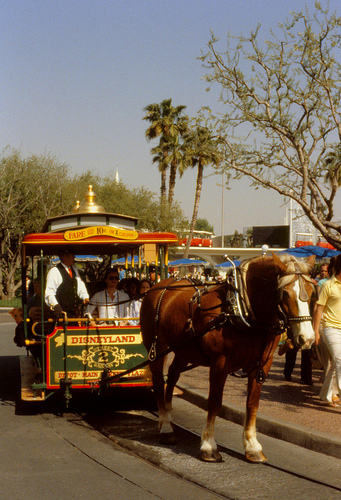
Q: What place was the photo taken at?
A: It was taken at the road.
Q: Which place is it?
A: It is a road.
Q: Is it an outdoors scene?
A: Yes, it is outdoors.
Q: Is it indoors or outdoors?
A: It is outdoors.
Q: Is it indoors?
A: No, it is outdoors.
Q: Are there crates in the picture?
A: No, there are no crates.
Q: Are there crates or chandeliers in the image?
A: No, there are no crates or chandeliers.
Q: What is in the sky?
A: The clouds are in the sky.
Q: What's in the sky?
A: The clouds are in the sky.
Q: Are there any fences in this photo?
A: No, there are no fences.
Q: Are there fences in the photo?
A: No, there are no fences.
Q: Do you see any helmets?
A: No, there are no helmets.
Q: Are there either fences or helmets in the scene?
A: No, there are no helmets or fences.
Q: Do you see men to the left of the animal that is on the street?
A: Yes, there is a man to the left of the horse.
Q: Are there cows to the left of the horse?
A: No, there is a man to the left of the horse.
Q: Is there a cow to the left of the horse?
A: No, there is a man to the left of the horse.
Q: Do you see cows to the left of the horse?
A: No, there is a man to the left of the horse.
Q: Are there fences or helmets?
A: No, there are no helmets or fences.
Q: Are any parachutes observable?
A: No, there are no parachutes.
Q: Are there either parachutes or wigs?
A: No, there are no parachutes or wigs.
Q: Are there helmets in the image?
A: No, there are no helmets.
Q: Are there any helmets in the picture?
A: No, there are no helmets.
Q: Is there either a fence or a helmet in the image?
A: No, there are no helmets or fences.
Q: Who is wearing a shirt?
A: The man is wearing a shirt.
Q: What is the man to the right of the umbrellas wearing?
A: The man is wearing a shirt.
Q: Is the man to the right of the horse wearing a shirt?
A: Yes, the man is wearing a shirt.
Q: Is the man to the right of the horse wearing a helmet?
A: No, the man is wearing a shirt.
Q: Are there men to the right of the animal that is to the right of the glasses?
A: Yes, there is a man to the right of the horse.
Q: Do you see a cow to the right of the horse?
A: No, there is a man to the right of the horse.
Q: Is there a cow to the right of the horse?
A: No, there is a man to the right of the horse.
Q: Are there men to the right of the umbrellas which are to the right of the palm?
A: Yes, there is a man to the right of the umbrellas.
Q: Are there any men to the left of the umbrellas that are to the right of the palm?
A: No, the man is to the right of the umbrellas.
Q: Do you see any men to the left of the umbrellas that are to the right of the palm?
A: No, the man is to the right of the umbrellas.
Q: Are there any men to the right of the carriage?
A: Yes, there is a man to the right of the carriage.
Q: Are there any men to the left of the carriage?
A: No, the man is to the right of the carriage.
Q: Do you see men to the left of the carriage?
A: No, the man is to the right of the carriage.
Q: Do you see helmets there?
A: No, there are no helmets.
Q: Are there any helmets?
A: No, there are no helmets.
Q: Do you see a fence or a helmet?
A: No, there are no helmets or fences.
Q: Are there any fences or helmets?
A: No, there are no helmets or fences.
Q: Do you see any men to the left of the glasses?
A: Yes, there is a man to the left of the glasses.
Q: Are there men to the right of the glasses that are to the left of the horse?
A: No, the man is to the left of the glasses.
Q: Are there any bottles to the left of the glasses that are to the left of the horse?
A: No, there is a man to the left of the glasses.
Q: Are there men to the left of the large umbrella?
A: Yes, there is a man to the left of the umbrella.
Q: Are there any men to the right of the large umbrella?
A: No, the man is to the left of the umbrella.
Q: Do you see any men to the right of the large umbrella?
A: No, the man is to the left of the umbrella.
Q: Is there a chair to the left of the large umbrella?
A: No, there is a man to the left of the umbrella.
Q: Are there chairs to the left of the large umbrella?
A: No, there is a man to the left of the umbrella.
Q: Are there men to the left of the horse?
A: Yes, there is a man to the left of the horse.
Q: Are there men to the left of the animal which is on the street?
A: Yes, there is a man to the left of the horse.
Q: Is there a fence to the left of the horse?
A: No, there is a man to the left of the horse.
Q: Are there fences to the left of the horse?
A: No, there is a man to the left of the horse.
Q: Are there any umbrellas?
A: Yes, there is an umbrella.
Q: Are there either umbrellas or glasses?
A: Yes, there is an umbrella.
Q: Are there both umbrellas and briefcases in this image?
A: No, there is an umbrella but no briefcases.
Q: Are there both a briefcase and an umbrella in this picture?
A: No, there is an umbrella but no briefcases.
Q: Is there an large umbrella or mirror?
A: Yes, there is a large umbrella.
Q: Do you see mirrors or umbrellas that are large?
A: Yes, the umbrella is large.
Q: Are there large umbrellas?
A: Yes, there is a large umbrella.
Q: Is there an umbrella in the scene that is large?
A: Yes, there is a large umbrella.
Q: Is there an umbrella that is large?
A: Yes, there is an umbrella that is large.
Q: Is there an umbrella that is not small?
A: Yes, there is a large umbrella.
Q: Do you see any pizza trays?
A: No, there are no pizza trays.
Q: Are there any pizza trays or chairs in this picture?
A: No, there are no pizza trays or chairs.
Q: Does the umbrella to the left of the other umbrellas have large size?
A: Yes, the umbrella is large.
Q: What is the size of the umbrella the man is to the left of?
A: The umbrella is large.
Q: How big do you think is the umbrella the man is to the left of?
A: The umbrella is large.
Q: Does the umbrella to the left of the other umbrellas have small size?
A: No, the umbrella is large.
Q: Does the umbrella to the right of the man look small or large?
A: The umbrella is large.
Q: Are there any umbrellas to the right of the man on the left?
A: Yes, there is an umbrella to the right of the man.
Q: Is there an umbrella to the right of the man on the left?
A: Yes, there is an umbrella to the right of the man.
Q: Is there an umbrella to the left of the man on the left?
A: No, the umbrella is to the right of the man.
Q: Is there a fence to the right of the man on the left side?
A: No, there is an umbrella to the right of the man.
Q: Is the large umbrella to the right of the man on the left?
A: Yes, the umbrella is to the right of the man.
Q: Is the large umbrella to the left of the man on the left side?
A: No, the umbrella is to the right of the man.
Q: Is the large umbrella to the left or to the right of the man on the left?
A: The umbrella is to the right of the man.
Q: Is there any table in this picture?
A: Yes, there is a table.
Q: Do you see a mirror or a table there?
A: Yes, there is a table.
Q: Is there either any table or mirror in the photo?
A: Yes, there is a table.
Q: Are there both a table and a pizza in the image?
A: No, there is a table but no pizzas.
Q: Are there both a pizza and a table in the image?
A: No, there is a table but no pizzas.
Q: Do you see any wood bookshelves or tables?
A: Yes, there is a wood table.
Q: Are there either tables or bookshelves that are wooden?
A: Yes, the table is wooden.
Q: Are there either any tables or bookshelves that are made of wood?
A: Yes, the table is made of wood.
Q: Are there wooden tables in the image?
A: Yes, there is a wood table.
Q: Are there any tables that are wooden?
A: Yes, there is a wood table.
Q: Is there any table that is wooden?
A: Yes, there is a table that is wooden.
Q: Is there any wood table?
A: Yes, there is a table that is made of wood.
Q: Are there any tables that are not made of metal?
A: Yes, there is a table that is made of wood.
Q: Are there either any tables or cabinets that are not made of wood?
A: No, there is a table but it is made of wood.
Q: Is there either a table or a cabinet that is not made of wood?
A: No, there is a table but it is made of wood.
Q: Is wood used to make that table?
A: Yes, the table is made of wood.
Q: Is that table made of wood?
A: Yes, the table is made of wood.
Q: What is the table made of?
A: The table is made of wood.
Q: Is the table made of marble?
A: No, the table is made of wood.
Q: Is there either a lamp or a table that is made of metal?
A: No, there is a table but it is made of wood.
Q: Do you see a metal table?
A: No, there is a table but it is made of wood.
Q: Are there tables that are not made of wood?
A: No, there is a table but it is made of wood.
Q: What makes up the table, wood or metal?
A: The table is made of wood.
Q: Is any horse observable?
A: Yes, there is a horse.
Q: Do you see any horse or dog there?
A: Yes, there is a horse.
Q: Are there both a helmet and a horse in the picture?
A: No, there is a horse but no helmets.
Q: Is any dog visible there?
A: No, there are no dogs.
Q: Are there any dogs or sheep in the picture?
A: No, there are no dogs or sheep.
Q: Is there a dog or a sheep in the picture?
A: No, there are no dogs or sheep.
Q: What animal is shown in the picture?
A: The animal is a horse.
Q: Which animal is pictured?
A: The animal is a horse.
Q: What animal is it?
A: The animal is a horse.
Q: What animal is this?
A: This is a horse.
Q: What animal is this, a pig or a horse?
A: This is a horse.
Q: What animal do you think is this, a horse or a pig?
A: This is a horse.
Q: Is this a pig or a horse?
A: This is a horse.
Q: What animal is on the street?
A: The horse is on the street.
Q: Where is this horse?
A: The horse is on the street.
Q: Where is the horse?
A: The horse is on the street.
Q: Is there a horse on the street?
A: Yes, there is a horse on the street.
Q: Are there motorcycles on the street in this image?
A: No, there is a horse on the street.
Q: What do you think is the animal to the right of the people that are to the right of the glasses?
A: The animal is a horse.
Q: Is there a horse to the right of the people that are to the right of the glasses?
A: Yes, there is a horse to the right of the people.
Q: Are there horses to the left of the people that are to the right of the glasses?
A: No, the horse is to the right of the people.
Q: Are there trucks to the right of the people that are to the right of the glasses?
A: No, there is a horse to the right of the people.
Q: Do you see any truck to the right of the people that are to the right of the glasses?
A: No, there is a horse to the right of the people.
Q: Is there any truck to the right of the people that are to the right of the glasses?
A: No, there is a horse to the right of the people.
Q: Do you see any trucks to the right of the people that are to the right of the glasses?
A: No, there is a horse to the right of the people.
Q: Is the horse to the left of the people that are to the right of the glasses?
A: No, the horse is to the right of the people.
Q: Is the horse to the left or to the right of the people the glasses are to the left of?
A: The horse is to the right of the people.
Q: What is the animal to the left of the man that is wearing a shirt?
A: The animal is a horse.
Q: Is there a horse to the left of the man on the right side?
A: Yes, there is a horse to the left of the man.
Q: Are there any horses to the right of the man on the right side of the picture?
A: No, the horse is to the left of the man.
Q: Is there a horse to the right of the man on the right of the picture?
A: No, the horse is to the left of the man.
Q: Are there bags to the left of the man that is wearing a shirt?
A: No, there is a horse to the left of the man.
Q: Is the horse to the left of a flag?
A: No, the horse is to the left of a man.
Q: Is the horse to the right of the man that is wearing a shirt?
A: No, the horse is to the left of the man.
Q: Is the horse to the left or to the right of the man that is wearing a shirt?
A: The horse is to the left of the man.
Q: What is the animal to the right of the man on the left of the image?
A: The animal is a horse.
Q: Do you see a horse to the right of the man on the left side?
A: Yes, there is a horse to the right of the man.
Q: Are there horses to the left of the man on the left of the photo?
A: No, the horse is to the right of the man.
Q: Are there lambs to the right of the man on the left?
A: No, there is a horse to the right of the man.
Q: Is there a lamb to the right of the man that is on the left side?
A: No, there is a horse to the right of the man.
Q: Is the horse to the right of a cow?
A: No, the horse is to the right of a man.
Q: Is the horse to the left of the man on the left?
A: No, the horse is to the right of the man.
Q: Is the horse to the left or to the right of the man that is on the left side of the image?
A: The horse is to the right of the man.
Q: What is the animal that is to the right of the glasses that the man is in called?
A: The animal is a horse.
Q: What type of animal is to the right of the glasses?
A: The animal is a horse.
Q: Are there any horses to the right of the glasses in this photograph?
A: Yes, there is a horse to the right of the glasses.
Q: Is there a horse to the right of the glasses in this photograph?
A: Yes, there is a horse to the right of the glasses.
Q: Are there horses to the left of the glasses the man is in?
A: No, the horse is to the right of the glasses.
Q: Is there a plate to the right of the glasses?
A: No, there is a horse to the right of the glasses.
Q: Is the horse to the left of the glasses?
A: No, the horse is to the right of the glasses.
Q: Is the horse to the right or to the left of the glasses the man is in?
A: The horse is to the right of the glasses.